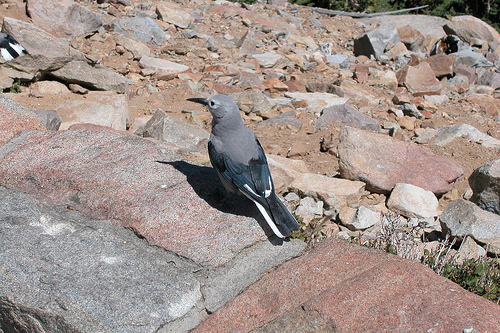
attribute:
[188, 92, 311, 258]
bird — gray, black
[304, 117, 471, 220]
rock — large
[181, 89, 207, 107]
beak — black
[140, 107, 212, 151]
rock — large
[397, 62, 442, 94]
rock — colorful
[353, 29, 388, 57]
rock — colorful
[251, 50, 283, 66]
rock — colorful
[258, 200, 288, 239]
tail feather — white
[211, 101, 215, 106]
eye — black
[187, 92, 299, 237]
bird — small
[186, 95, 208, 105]
beak — black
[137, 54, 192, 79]
rock — colorful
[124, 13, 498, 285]
rocks — brown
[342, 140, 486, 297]
brick — red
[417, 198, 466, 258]
grass — green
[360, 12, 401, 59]
rock — large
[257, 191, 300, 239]
tail — black, feathered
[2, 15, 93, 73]
rock — large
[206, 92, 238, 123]
head — gray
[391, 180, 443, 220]
rock — white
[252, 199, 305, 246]
feathers — black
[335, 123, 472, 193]
rock — large, colorful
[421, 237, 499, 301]
bush — small, green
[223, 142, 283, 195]
feathers — dark blue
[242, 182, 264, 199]
stripe — white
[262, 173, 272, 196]
stripe — white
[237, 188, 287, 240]
stripe — white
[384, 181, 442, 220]
rock — large